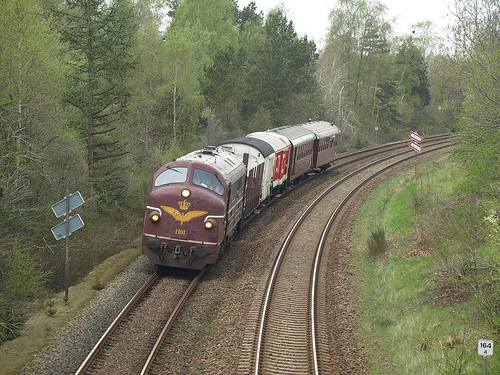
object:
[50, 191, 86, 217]
sign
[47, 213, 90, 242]
sign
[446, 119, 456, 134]
ground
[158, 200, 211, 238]
design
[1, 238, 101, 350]
grass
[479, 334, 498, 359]
sign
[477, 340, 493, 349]
lettering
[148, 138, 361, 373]
gravel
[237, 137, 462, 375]
track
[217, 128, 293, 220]
car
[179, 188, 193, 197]
lights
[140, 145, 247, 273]
car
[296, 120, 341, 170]
car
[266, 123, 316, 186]
car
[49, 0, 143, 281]
tree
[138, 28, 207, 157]
tree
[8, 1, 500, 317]
area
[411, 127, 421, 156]
signs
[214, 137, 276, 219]
cart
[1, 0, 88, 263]
trees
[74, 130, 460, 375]
track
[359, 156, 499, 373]
grass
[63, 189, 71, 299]
pole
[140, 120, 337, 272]
train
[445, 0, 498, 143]
foliage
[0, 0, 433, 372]
foliage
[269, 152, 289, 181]
lettering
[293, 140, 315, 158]
windows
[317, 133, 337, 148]
windows